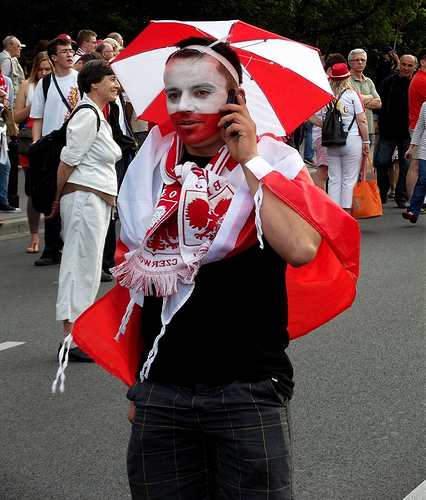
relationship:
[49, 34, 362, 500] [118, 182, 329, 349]
man wearing shirt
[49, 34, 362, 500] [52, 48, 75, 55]
man wearing glasses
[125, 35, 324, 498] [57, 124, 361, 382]
man wearing umbrella hat flag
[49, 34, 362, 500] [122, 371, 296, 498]
man wearing umbrella hat pants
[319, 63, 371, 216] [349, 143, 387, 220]
lady carrying bag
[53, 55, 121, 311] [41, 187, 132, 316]
woman wearing pants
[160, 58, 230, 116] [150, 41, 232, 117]
paint on face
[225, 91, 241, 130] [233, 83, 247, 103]
phone on ear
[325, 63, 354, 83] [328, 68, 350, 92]
hat on head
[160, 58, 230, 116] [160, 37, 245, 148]
paint on face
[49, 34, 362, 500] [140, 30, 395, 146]
man on phone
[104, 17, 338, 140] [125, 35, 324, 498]
sunhat on man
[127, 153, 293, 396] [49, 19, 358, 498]
shirt on man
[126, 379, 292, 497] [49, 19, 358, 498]
pants on man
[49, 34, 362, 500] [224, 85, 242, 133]
man on phone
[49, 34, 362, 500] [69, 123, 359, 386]
man wearing cape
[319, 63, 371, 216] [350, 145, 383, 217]
lady holding bag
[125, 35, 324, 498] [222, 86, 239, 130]
man holding phone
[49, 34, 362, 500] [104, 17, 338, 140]
man wearing sunhat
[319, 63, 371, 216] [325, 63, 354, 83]
lady wearing hat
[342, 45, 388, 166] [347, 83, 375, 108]
man has arm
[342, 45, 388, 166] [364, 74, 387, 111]
man has arm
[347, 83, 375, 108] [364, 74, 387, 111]
arm folded over arm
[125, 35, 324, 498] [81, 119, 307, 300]
man wearing scarf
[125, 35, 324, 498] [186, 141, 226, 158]
man has neck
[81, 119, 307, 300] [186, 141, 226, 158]
scarf on neck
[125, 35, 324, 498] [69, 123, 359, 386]
man wearing cape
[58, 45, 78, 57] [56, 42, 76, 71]
glasses on man's face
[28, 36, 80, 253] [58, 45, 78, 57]
man wearing glasses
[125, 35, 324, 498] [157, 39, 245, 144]
man has head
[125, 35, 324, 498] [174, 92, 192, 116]
man has nose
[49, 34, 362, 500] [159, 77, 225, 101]
man has eyes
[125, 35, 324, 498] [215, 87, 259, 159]
man has hand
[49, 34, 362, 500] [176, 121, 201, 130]
man has lips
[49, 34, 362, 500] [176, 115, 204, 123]
man has lips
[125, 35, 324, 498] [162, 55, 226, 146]
man has face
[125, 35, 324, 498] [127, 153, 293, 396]
man wearing shirt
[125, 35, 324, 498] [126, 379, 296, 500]
man wearing pants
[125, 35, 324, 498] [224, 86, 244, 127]
man holding phone